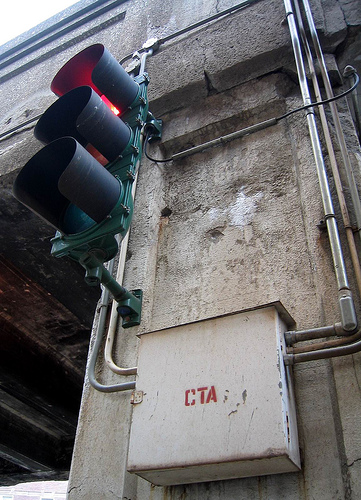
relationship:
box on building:
[125, 298, 303, 487] [0, 0, 359, 498]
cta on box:
[181, 384, 216, 404] [111, 318, 341, 485]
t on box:
[196, 385, 206, 404] [120, 303, 305, 488]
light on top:
[46, 36, 108, 89] [11, 41, 148, 264]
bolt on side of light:
[125, 168, 138, 182] [8, 41, 161, 268]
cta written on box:
[158, 359, 229, 409] [120, 303, 305, 488]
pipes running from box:
[78, 0, 359, 392] [125, 298, 303, 487]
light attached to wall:
[19, 49, 149, 272] [139, 2, 359, 496]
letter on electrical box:
[180, 393, 195, 413] [143, 302, 316, 433]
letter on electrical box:
[196, 376, 206, 404] [143, 302, 316, 433]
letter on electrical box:
[205, 380, 220, 405] [143, 302, 316, 433]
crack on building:
[203, 66, 219, 100] [0, 0, 359, 498]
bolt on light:
[119, 199, 131, 220] [7, 41, 158, 329]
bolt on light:
[133, 117, 145, 126] [12, 40, 145, 303]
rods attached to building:
[291, 35, 341, 276] [0, 0, 359, 498]